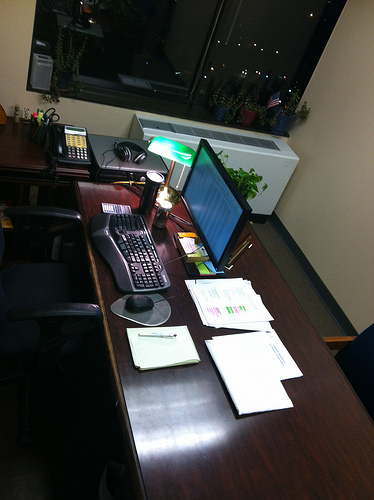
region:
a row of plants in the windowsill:
[202, 68, 310, 137]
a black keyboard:
[87, 203, 172, 294]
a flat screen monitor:
[177, 127, 251, 271]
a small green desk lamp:
[145, 130, 194, 206]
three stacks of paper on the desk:
[120, 270, 302, 417]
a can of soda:
[152, 198, 172, 231]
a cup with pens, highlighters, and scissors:
[26, 101, 60, 144]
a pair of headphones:
[110, 136, 147, 166]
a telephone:
[45, 120, 97, 171]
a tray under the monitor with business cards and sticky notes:
[172, 226, 217, 276]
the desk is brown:
[71, 171, 372, 496]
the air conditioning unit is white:
[121, 108, 306, 228]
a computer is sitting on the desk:
[87, 136, 254, 310]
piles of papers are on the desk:
[115, 272, 313, 433]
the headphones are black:
[77, 129, 158, 187]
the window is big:
[18, 0, 349, 144]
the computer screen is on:
[168, 135, 255, 282]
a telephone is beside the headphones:
[42, 113, 154, 178]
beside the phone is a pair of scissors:
[30, 101, 94, 169]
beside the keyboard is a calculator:
[83, 193, 171, 314]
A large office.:
[7, 20, 353, 446]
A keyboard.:
[92, 201, 170, 295]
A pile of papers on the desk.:
[124, 265, 291, 400]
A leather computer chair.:
[0, 198, 106, 342]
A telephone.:
[44, 121, 94, 163]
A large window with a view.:
[26, 0, 348, 135]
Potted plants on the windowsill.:
[167, 81, 321, 124]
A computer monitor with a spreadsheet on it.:
[174, 137, 252, 286]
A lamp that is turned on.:
[139, 121, 189, 209]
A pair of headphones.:
[99, 132, 147, 174]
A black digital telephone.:
[48, 117, 91, 166]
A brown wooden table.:
[140, 419, 373, 499]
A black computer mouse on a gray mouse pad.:
[110, 293, 171, 326]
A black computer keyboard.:
[87, 210, 171, 292]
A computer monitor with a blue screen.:
[181, 138, 252, 268]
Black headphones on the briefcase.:
[102, 140, 150, 168]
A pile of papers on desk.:
[184, 276, 304, 415]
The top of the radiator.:
[134, 108, 299, 163]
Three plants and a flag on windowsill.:
[208, 85, 314, 137]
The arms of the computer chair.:
[0, 203, 99, 320]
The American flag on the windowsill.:
[267, 88, 283, 112]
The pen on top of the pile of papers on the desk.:
[136, 329, 180, 342]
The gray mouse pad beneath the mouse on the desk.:
[109, 289, 173, 325]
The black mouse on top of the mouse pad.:
[123, 291, 159, 313]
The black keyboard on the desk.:
[91, 213, 171, 292]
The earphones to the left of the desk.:
[110, 136, 150, 163]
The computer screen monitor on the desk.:
[171, 142, 260, 268]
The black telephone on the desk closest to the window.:
[49, 119, 96, 173]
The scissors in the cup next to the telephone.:
[43, 108, 59, 126]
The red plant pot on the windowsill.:
[241, 84, 260, 129]